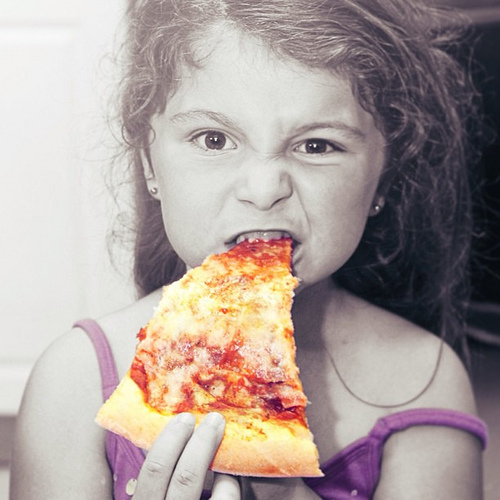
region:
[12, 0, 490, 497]
a girl angry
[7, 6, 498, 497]
a small girl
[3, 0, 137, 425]
a white wall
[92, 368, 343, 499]
a pizza crust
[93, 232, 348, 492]
a cheese pizza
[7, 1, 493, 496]
A CHILD EATING PIZZA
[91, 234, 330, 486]
A SLICE OF CHEESE PIZZA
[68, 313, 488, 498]
A CHILD'S PURPLE TANK TOP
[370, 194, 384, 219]
A CHILD' EARRING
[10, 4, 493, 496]
A CHILD BITING INTO A SLICE OF PIZZA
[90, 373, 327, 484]
PIZZA CRUST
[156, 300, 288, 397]
CHEESE ON A PIZZA SLICE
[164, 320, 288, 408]
TOMATO SAUCE AND CHEESE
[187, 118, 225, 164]
eye of the girl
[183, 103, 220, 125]
eyebrow of the girl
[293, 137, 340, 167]
a eye of the girl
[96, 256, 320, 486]
a piece of pizza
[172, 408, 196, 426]
fingernail on the child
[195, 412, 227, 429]
fingernail on the girl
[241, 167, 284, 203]
the girls nose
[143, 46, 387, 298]
a girls face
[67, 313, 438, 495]
girl is wearing a purple dress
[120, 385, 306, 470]
crust of the pizza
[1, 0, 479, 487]
this is a girl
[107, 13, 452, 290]
the face of a girl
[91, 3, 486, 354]
the long hair of a girl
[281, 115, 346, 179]
the eye of a girl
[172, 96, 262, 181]
the eye of a girl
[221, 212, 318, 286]
the mouth of a girl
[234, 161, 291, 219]
the nose of a girl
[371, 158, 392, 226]
the ear of a girl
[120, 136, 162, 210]
the ear of a girl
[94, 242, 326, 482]
a slice of pizza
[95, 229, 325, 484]
The girl is holding a slice of pizza.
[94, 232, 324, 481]
The girl is eating a slice of pizza.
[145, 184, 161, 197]
The girls right ear has an earring.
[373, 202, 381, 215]
The girls left ear has an earring.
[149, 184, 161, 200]
The earring is round.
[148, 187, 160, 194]
The earring is silver.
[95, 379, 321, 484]
The pizza crust is brown.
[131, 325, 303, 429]
The pizza sauce is red.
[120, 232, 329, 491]
Piece of a pizza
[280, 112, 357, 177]
Eye of a child